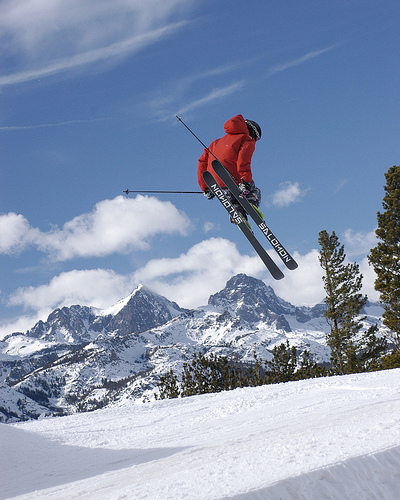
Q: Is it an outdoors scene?
A: Yes, it is outdoors.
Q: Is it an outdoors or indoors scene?
A: It is outdoors.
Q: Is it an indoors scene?
A: No, it is outdoors.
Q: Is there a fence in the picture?
A: No, there are no fences.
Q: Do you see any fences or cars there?
A: No, there are no fences or cars.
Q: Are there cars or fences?
A: No, there are no fences or cars.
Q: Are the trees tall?
A: Yes, the trees are tall.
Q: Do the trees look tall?
A: Yes, the trees are tall.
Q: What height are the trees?
A: The trees are tall.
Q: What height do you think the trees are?
A: The trees are tall.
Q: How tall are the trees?
A: The trees are tall.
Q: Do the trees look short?
A: No, the trees are tall.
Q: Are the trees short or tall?
A: The trees are tall.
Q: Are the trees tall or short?
A: The trees are tall.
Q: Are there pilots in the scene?
A: No, there are no pilots.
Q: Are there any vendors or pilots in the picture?
A: No, there are no pilots or vendors.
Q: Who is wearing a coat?
A: The man is wearing a coat.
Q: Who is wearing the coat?
A: The man is wearing a coat.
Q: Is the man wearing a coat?
A: Yes, the man is wearing a coat.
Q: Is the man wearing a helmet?
A: No, the man is wearing a coat.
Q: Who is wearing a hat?
A: The man is wearing a hat.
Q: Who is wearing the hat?
A: The man is wearing a hat.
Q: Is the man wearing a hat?
A: Yes, the man is wearing a hat.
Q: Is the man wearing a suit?
A: No, the man is wearing a hat.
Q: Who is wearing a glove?
A: The man is wearing a glove.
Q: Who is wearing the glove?
A: The man is wearing a glove.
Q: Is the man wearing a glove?
A: Yes, the man is wearing a glove.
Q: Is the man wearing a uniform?
A: No, the man is wearing a glove.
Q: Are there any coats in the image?
A: Yes, there is a coat.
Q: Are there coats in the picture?
A: Yes, there is a coat.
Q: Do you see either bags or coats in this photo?
A: Yes, there is a coat.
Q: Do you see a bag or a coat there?
A: Yes, there is a coat.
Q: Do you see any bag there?
A: No, there are no bags.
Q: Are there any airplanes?
A: No, there are no airplanes.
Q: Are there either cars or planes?
A: No, there are no planes or cars.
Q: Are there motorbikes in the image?
A: No, there are no motorbikes.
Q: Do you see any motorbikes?
A: No, there are no motorbikes.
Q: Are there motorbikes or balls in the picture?
A: No, there are no motorbikes or balls.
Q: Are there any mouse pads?
A: No, there are no mouse pads.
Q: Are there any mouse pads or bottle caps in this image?
A: No, there are no mouse pads or bottle caps.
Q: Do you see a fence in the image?
A: No, there are no fences.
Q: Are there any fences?
A: No, there are no fences.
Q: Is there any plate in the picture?
A: No, there are no plates.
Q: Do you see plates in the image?
A: No, there are no plates.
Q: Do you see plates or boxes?
A: No, there are no plates or boxes.